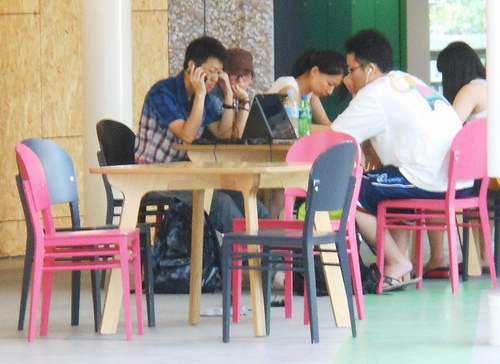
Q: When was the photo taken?
A: Daytime.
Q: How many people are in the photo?
A: Five.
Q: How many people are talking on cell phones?
A: One.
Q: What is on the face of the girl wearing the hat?
A: Glasses.